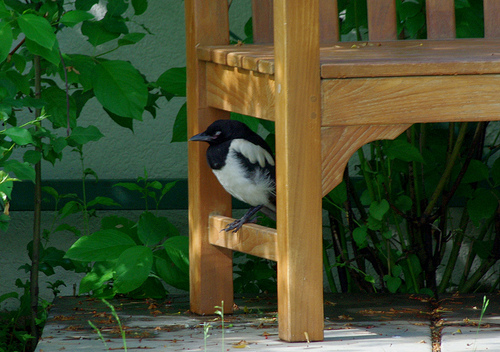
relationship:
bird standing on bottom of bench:
[188, 118, 280, 234] [177, 0, 498, 345]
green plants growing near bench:
[0, 3, 499, 308] [177, 0, 498, 345]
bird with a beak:
[185, 118, 279, 234] [188, 124, 217, 149]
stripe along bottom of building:
[7, 174, 191, 216] [1, 0, 499, 221]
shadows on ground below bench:
[37, 278, 497, 343] [177, 0, 498, 345]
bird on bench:
[188, 118, 280, 234] [177, 0, 498, 345]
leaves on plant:
[4, 0, 160, 186] [9, 4, 162, 339]